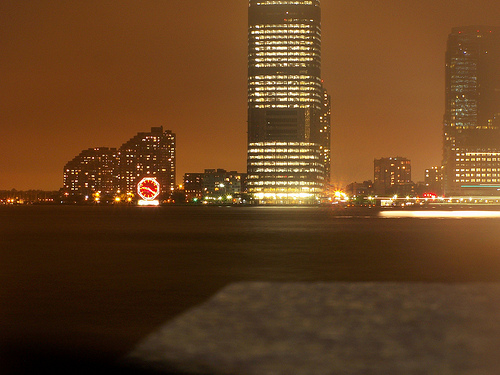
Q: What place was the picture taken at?
A: It was taken at the city.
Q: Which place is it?
A: It is a city.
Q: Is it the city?
A: Yes, it is the city.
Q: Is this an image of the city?
A: Yes, it is showing the city.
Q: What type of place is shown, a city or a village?
A: It is a city.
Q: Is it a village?
A: No, it is a city.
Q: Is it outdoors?
A: Yes, it is outdoors.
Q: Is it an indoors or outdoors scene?
A: It is outdoors.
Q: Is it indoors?
A: No, it is outdoors.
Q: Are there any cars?
A: No, there are no cars.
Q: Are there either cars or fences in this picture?
A: No, there are no cars or fences.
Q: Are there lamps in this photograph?
A: No, there are no lamps.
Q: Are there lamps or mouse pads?
A: No, there are no lamps or mouse pads.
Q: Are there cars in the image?
A: No, there are no cars.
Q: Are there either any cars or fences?
A: No, there are no cars or fences.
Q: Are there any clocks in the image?
A: Yes, there is a clock.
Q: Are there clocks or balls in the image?
A: Yes, there is a clock.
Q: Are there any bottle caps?
A: No, there are no bottle caps.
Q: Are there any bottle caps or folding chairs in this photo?
A: No, there are no bottle caps or folding chairs.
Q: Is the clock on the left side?
A: Yes, the clock is on the left of the image.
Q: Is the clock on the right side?
A: No, the clock is on the left of the image.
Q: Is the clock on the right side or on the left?
A: The clock is on the left of the image.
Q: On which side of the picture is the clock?
A: The clock is on the left of the image.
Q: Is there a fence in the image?
A: No, there are no fences.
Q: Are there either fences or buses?
A: No, there are no fences or buses.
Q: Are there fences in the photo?
A: No, there are no fences.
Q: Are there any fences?
A: No, there are no fences.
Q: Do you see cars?
A: No, there are no cars.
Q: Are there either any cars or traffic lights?
A: No, there are no cars or traffic lights.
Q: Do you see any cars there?
A: No, there are no cars.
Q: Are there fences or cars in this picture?
A: No, there are no cars or fences.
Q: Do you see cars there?
A: No, there are no cars.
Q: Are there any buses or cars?
A: No, there are no cars or buses.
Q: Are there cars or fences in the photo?
A: No, there are no cars or fences.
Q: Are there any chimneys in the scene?
A: No, there are no chimneys.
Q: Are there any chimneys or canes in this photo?
A: No, there are no chimneys or canes.